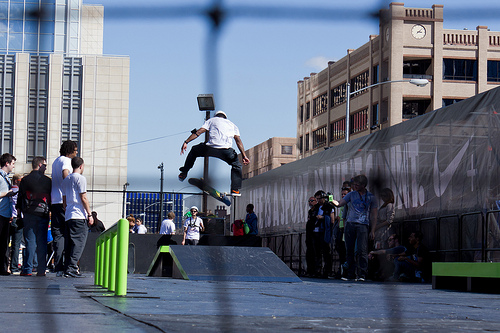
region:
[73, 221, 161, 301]
The pole is green.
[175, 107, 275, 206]
The man is wearing a hat.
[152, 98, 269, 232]
The man is wearing a white shirt.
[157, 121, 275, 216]
The man is wearing jeans.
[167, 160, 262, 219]
The skateboard is black.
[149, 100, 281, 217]
He is skateboarding.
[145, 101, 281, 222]
The man is doing a trick.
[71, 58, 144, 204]
The building is tan.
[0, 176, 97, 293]
They are watching.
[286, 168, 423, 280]
The are standing on the side.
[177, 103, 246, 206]
young man on a skateboard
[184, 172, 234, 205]
a black skateboard in air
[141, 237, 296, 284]
a black skateboard ramp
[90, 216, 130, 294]
a bright green railing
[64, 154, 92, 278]
spectator watching skateboarder perform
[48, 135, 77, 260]
spectator watching skateboarder perform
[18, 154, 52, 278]
spectator watching skateboarder perform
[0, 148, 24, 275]
spectator watching skateboarder perform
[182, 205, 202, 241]
spectator watching skateboarder perform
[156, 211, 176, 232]
spectator watching skateboarder perform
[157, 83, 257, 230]
person riding on skateboard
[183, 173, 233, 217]
skateboard in mid air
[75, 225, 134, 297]
lime green fence on side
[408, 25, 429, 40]
clock on side of building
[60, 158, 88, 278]
guy in white tshirt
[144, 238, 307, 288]
low skate board ramp on ground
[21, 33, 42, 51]
window on front of building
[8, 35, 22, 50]
window on front of building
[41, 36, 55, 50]
window on front of building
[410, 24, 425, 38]
White clock on building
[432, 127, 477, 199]
White Nike logo on banner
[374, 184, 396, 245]
Woman leaning against banner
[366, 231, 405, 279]
Man sitting next to standing woman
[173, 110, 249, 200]
Man doing skateboarding trick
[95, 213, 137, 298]
Green skateboarding rail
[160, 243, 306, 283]
Black ramp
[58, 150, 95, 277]
Man watching man doing skateboarding trick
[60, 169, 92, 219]
T-shirt is white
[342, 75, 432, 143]
Light post is tall and gray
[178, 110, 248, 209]
skateboarder in mid air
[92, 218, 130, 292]
bright green railing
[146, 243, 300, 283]
black ramp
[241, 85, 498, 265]
large screen with Nike logo on it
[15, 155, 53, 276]
man standing wearing black jacket with a red and black backpack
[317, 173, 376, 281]
man standing on side with blue shirt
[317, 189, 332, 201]
camera held by man in blue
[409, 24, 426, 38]
clock on building in background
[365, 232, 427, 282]
two people sitting against the side